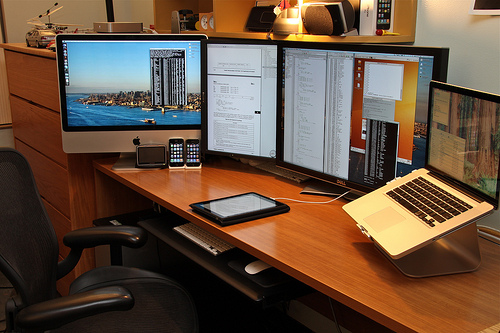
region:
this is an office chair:
[0, 205, 186, 329]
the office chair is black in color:
[5, 167, 182, 327]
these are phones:
[167, 134, 204, 171]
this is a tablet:
[186, 180, 291, 226]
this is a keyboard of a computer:
[145, 220, 280, 282]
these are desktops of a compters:
[57, 35, 281, 161]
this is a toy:
[21, 24, 55, 47]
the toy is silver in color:
[20, 26, 56, 48]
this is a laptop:
[343, 80, 498, 260]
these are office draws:
[1, 45, 65, 212]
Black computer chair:
[0, 145, 148, 332]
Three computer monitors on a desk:
[47, 26, 438, 168]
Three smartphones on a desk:
[115, 136, 202, 171]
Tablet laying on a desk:
[187, 175, 290, 239]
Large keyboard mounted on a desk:
[325, 162, 485, 256]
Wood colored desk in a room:
[97, 142, 498, 332]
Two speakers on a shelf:
[238, 1, 364, 43]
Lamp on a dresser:
[92, 0, 146, 37]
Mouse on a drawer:
[230, 256, 294, 293]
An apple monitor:
[123, 132, 150, 151]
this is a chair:
[9, 157, 146, 327]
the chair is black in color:
[134, 284, 169, 324]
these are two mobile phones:
[170, 138, 199, 170]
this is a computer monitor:
[55, 40, 203, 131]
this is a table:
[279, 225, 316, 275]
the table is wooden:
[293, 222, 328, 254]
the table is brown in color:
[295, 227, 327, 265]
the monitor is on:
[86, 46, 123, 88]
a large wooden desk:
[115, 163, 492, 330]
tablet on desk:
[198, 177, 278, 243]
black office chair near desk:
[0, 140, 215, 320]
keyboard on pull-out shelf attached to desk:
[137, 186, 287, 296]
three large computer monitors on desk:
[55, 35, 432, 228]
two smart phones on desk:
[160, 120, 210, 190]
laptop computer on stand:
[352, 85, 497, 288]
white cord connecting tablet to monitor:
[232, 170, 362, 216]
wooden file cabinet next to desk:
[1, 43, 186, 270]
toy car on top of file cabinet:
[9, 24, 60, 142]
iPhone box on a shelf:
[371, 0, 396, 35]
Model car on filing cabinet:
[21, 28, 56, 48]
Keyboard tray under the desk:
[127, 200, 264, 305]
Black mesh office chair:
[2, 148, 186, 330]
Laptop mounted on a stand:
[347, 77, 498, 284]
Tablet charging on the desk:
[190, 188, 289, 230]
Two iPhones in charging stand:
[168, 136, 203, 172]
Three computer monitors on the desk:
[53, 32, 431, 191]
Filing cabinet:
[1, 40, 82, 288]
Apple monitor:
[53, 33, 206, 152]